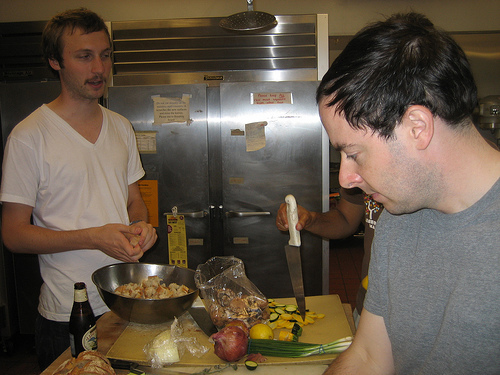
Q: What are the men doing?
A: Making food.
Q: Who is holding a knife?
A: The person behind the man in the grey shirt.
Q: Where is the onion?
A: On the table.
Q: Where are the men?
A: A commercial kitchen.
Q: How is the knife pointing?
A: Down to the table.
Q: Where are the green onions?
A: On the table.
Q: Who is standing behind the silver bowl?
A: A man in a white t-shirt.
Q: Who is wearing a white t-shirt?
A: The man behind the silver bowl.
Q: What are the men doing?
A: Preparing food.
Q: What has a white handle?
A: Knife.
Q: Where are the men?
A: In a kitchen.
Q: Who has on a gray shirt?
A: Guy on the right.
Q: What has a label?
A: Bottle.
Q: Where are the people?
A: A kitchen.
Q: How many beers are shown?
A: One.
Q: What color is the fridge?
A: Silver.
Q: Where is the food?
A: Cutting board.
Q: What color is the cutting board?
A: Brown.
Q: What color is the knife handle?
A: White.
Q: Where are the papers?
A: On fridge.